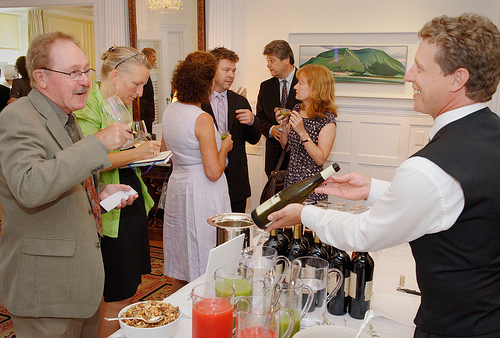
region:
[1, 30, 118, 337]
a man in a suit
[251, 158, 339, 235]
a bottle of champagne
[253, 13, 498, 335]
a man holding a bottle of champagne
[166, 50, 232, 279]
a woman in a white dress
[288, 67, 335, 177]
a woman in a black and white dress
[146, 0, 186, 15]
a chandelier on the ceiling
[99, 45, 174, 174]
a woman writing in a notebook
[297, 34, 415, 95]
a picture on the wall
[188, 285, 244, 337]
a pitcher with a red drink in it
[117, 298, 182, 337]
a white bowl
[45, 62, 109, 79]
The man is wearing glasses.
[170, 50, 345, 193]
People in a group talking.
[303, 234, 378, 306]
Wine bottles on the table.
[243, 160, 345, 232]
The waiter is holding a wine bottle in hand.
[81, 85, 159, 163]
The man is sipping on wine.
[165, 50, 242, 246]
the lady is wearing a white dress.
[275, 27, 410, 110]
A picture on the wall.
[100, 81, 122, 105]
The lady is wearing hoop earrings.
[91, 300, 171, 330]
A spoon in the bowl.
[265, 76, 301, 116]
The man has on a tie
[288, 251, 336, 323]
A pitcher or water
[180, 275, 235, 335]
A pitcher with a red drink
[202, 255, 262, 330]
A pitcher with a green drink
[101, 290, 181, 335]
A white bowl of food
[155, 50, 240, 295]
A woman in a white dress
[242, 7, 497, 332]
A man wearing a black vest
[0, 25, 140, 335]
A man wearing a brown suit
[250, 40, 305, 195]
A man wearing a striped tie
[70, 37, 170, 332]
A woman writing in a notebook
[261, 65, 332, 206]
A woman with a brown purse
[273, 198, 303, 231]
MAN IS HOLDING A WINE BOTTLE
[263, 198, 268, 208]
WINE BOTTLE HAS A LABEL ON IT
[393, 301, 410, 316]
TABLE CLOTH ON THE TABLE IS WHITE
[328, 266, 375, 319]
WINE BOTTLES ARE SITTING ON THE TABLE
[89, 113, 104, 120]
WOMAN HAS ON A GREEN JACKET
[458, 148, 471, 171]
MAN IS WEARING A BLACK VEST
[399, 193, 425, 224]
MAN HAS ON A LONG SLEEVE SHIRT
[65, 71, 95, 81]
MAN IS WEARING EYE GLASSES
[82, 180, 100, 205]
MAN HAS ON ANECK TIE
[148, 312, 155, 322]
SPOON IS IN THE BOWL